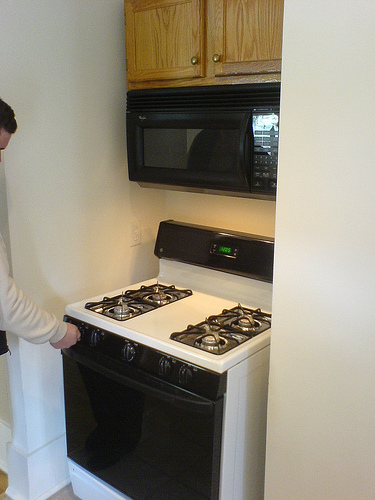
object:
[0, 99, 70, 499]
man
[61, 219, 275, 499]
stove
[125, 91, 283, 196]
microwave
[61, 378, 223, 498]
door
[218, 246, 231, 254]
clock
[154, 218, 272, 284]
part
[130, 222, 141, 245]
outlet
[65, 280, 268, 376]
range top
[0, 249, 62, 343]
arm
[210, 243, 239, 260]
display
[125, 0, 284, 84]
cabinet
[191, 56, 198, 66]
knob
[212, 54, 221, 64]
knob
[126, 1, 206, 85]
door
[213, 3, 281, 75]
door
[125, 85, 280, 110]
vent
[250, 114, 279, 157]
daylight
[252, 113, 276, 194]
control panel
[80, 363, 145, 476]
reflection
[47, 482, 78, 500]
floor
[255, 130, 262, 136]
button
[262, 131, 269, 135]
button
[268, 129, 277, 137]
button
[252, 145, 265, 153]
button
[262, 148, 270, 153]
button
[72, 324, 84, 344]
dial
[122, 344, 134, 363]
dial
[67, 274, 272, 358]
stove top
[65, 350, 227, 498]
window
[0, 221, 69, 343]
shirt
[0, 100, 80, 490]
person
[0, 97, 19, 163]
head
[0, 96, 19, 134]
hair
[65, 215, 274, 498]
oven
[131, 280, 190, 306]
burner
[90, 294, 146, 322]
burner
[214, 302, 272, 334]
burner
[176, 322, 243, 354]
burner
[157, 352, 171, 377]
dials